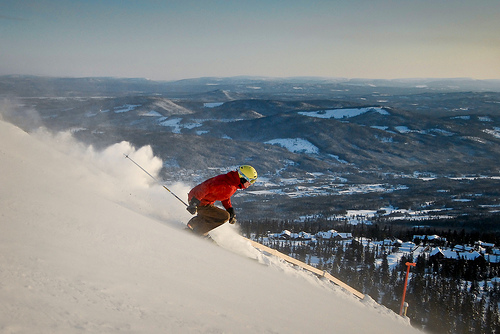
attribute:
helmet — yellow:
[233, 157, 277, 201]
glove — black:
[182, 191, 199, 215]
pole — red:
[393, 256, 418, 316]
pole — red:
[398, 260, 417, 317]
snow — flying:
[297, 103, 392, 118]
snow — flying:
[266, 134, 319, 155]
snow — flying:
[327, 204, 458, 224]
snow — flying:
[367, 122, 392, 131]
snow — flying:
[0, 114, 436, 330]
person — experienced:
[180, 162, 262, 242]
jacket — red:
[186, 171, 241, 210]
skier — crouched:
[187, 164, 260, 233]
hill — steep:
[1, 116, 422, 331]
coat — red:
[187, 170, 243, 205]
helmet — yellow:
[237, 164, 259, 180]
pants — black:
[180, 197, 213, 237]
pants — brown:
[189, 202, 230, 239]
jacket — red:
[191, 170, 234, 207]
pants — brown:
[188, 204, 230, 235]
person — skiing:
[183, 169, 254, 229]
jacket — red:
[187, 180, 254, 207]